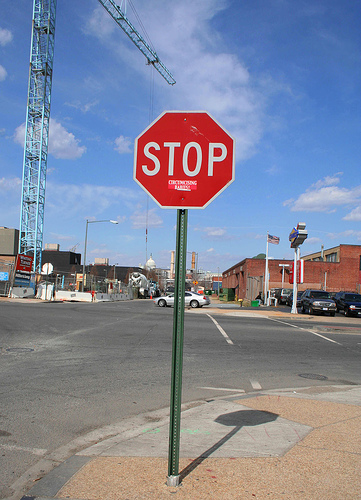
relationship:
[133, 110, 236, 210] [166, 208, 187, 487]
sign on pole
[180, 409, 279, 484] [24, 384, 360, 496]
shadow on sidewalk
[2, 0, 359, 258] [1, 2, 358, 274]
clouds are in sky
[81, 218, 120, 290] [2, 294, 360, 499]
light over street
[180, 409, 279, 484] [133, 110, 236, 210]
shadow of sign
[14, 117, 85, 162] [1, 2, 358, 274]
cloud in sky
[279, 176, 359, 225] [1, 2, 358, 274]
cloud in sky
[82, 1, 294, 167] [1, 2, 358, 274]
cloud in sky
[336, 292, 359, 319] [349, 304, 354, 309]
car has headlight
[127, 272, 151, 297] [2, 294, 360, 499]
mixer on street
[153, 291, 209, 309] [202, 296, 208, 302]
car has tail light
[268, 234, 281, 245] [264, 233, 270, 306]
flag on pole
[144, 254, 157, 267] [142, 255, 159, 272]
dome of building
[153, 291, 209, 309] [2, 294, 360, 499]
car on street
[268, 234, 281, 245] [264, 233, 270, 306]
flag waving on pole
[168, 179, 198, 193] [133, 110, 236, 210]
sticker on sign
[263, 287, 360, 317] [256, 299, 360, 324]
cars are in parking lot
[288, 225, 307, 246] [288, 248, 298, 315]
sign on pole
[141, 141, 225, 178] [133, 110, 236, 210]
letters are on sign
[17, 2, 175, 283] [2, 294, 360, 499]
crane near street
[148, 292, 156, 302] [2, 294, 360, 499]
cone on street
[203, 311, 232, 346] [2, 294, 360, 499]
line on street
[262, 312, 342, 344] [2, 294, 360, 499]
line on street